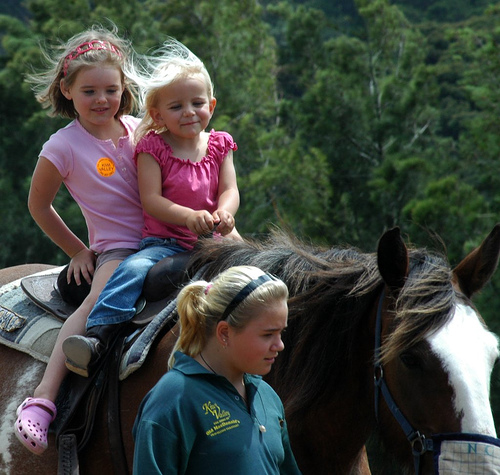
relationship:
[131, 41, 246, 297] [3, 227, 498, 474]
girl on horse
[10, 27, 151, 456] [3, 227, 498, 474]
girl on horse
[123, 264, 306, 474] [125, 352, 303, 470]
woman wearing shirt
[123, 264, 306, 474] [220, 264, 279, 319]
woman wearing headband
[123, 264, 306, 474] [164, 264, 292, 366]
woman has hair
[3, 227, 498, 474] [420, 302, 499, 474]
horse has face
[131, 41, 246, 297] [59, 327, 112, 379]
girl wearing shoes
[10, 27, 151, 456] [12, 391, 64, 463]
girl wearing shoes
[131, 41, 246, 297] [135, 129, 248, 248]
girl wearing shirt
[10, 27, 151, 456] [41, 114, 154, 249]
girl wearing shirt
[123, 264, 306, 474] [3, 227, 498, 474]
woman beside horse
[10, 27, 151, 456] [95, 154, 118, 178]
girl has sticker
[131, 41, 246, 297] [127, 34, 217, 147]
girl has hair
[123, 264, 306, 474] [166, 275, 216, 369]
woman has ponytail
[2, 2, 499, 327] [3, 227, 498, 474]
trees are behind horse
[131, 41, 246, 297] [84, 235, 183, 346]
girl wearing jeans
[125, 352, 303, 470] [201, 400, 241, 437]
shirt has writing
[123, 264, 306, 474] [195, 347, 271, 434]
woman wearing necklace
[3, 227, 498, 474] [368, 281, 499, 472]
horse wearing harness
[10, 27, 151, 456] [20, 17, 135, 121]
girl has hair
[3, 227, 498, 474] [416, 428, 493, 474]
horse has feedbag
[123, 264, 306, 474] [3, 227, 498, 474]
woman leading horse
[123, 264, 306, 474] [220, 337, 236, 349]
woman wearing earring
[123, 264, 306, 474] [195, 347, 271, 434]
woman has necklace